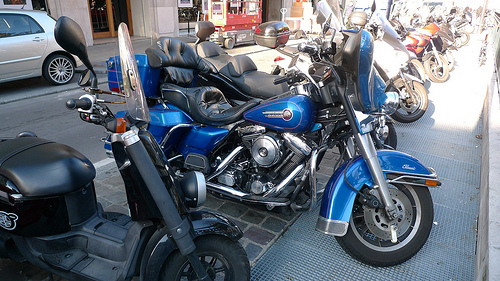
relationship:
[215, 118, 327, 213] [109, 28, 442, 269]
engine of motorcycle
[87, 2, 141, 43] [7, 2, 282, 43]
double door on building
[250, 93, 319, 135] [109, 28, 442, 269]
gas tank on motorcycle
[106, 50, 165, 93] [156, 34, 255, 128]
blue box behind seat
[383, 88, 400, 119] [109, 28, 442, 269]
headlight on motorcycle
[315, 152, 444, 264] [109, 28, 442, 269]
wheel on motorcycle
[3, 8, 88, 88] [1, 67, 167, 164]
car parked on road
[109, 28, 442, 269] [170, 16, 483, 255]
motorcycle parked on sidewalk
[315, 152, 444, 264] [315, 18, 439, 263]
wheel in front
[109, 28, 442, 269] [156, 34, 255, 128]
motorcycle has a black seat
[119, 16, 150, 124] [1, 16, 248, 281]
windshield on motorcycles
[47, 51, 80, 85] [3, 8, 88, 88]
wheel on car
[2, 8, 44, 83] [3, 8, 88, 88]
door on car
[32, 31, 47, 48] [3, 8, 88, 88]
handle on car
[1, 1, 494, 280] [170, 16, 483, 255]
motorcycles parked on sidewalk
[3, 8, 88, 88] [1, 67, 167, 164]
car on road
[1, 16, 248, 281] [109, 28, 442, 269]
motorcycles next to motorcycle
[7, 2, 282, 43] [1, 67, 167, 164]
building on road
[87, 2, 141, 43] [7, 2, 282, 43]
double door on front of building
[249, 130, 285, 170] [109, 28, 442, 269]
part of a motorcycle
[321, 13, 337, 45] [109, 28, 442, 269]
side mirror of motorcycle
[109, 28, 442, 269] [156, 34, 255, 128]
motorcycle has a seat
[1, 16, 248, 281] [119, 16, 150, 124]
motorcycles has windshield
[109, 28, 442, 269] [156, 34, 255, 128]
motorcycle has two seats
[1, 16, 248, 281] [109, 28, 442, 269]
motorcycles by motorcycle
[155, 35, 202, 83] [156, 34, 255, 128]
backrest on seat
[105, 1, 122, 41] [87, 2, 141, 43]
wood border on double door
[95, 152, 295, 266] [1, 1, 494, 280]
small bricks are for parking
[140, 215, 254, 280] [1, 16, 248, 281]
tire on motorcycles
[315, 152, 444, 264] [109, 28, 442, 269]
tire on motorcycle